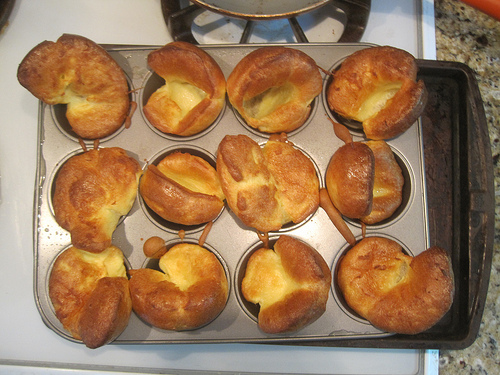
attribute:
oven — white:
[0, 0, 443, 373]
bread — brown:
[322, 41, 428, 143]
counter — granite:
[3, 6, 496, 373]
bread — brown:
[50, 145, 141, 253]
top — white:
[35, 37, 487, 344]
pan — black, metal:
[245, 60, 497, 348]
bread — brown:
[228, 134, 322, 229]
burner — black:
[165, 4, 381, 55]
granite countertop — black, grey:
[435, 0, 499, 374]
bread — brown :
[46, 240, 133, 351]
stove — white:
[17, 2, 428, 40]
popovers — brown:
[57, 53, 429, 328]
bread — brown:
[18, 39, 480, 350]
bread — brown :
[126, 243, 228, 329]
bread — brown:
[338, 41, 427, 143]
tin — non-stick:
[42, 42, 430, 344]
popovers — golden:
[12, 29, 464, 352]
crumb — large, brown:
[144, 235, 166, 259]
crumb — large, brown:
[322, 186, 339, 238]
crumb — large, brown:
[332, 118, 352, 143]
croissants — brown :
[325, 45, 430, 136]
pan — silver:
[9, 39, 449, 350]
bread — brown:
[217, 130, 320, 232]